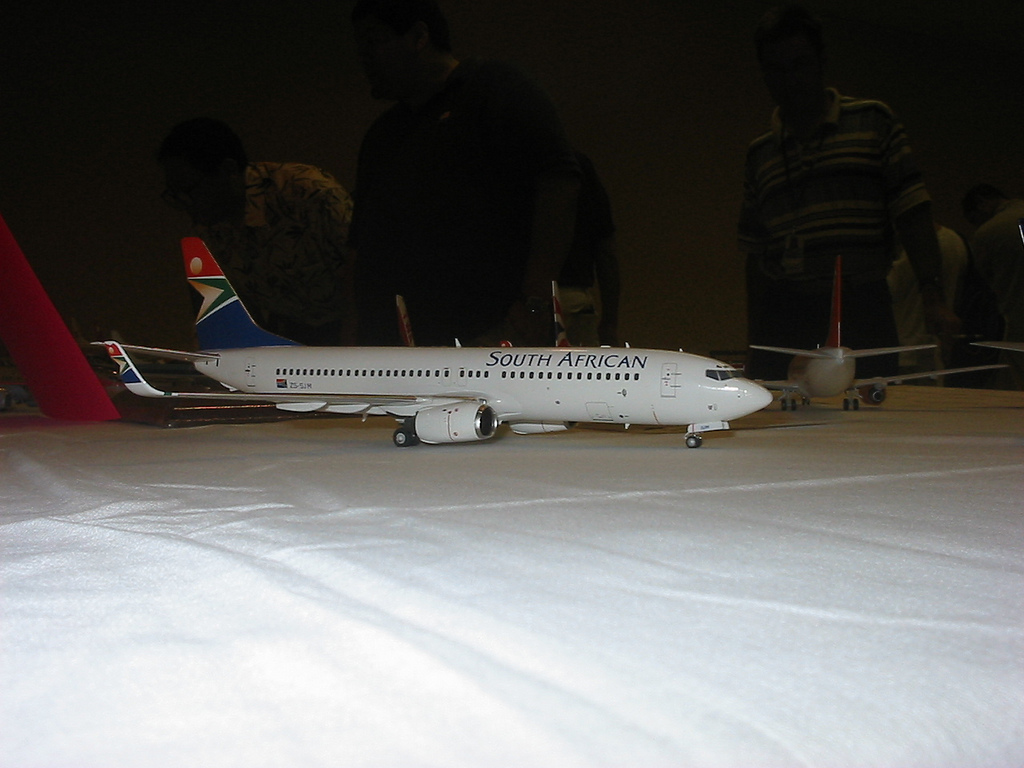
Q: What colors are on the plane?
A: Red, Blue and White.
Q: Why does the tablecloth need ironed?
A: It is wrinkled.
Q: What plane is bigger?
A: The one in front.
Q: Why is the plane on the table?
A: It is on display.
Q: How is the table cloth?
A: Wrinkled.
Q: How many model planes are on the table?
A: Two.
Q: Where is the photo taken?
A: On the taxiway.